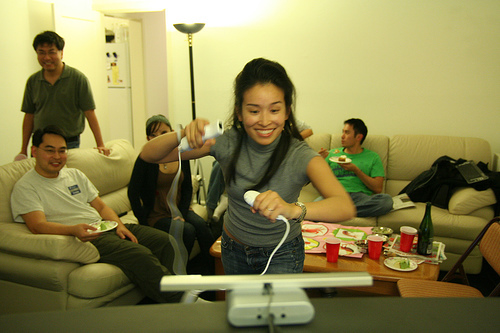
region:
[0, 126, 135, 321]
guy sitting on the couch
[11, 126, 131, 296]
guy wearing glasses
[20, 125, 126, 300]
guy holding a plate in his hand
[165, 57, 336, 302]
lady playing a game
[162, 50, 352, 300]
lady holding two controllers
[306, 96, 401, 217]
guy eating food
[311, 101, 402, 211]
guy holding plate up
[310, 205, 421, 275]
cups on the table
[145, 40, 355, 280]
lady wearing grey shirt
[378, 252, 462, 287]
plate on table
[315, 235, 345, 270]
Red plastic cup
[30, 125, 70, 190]
Smiling man wearing glasses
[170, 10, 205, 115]
Black and gold stand lamp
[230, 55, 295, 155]
Woman with a big smile on her face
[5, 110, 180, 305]
Two people sitting on a leather love seat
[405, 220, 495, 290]
Striped metal chair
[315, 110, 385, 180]
Man holding a plate of food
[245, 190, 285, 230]
Left hand with a ring on it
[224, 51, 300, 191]
Woman with dark long hair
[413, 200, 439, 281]
Green bottle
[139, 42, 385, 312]
woman playing Wii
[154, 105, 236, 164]
Wii controller in the hand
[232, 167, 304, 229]
white nunchuck in the hand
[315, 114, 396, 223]
man eating on the couch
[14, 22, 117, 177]
man standing behind the couch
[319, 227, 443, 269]
three red solo cups on the table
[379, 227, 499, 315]
chair by the corner of the table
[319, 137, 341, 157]
utensil with food on it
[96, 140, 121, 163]
hand resting on the couch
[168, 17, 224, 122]
tall black lamp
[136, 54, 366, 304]
A girl playing a wii.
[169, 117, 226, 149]
A white Wii controller.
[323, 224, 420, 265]
A red plastic cup.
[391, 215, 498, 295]
A brown foldable chair.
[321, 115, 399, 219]
A man sitting down eating.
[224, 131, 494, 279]
A cream colored couch.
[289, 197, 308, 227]
A wristwatch.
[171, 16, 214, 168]
A tall room light.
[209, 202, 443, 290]
A light brown, wooden coffee table.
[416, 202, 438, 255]
A green wine bottle.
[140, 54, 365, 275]
a woman playing a video game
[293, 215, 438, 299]
a table in the living room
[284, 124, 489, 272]
the couch in the living room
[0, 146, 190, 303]
the other couch in the living room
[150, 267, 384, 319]
the camera for the Nintendo Wii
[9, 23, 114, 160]
the man standing behind the couch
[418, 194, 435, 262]
a bottle sitting on the table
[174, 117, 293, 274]
the wiimote the woman is holding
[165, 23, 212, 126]
the light behind the couch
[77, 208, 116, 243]
the plate the man was holding